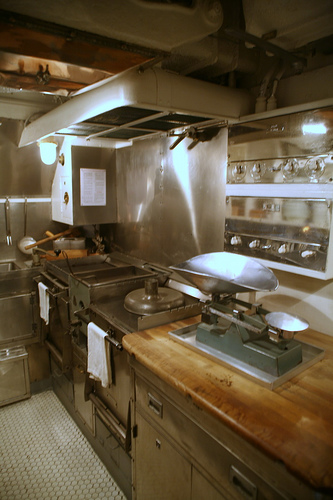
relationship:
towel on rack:
[86, 321, 113, 390] [72, 304, 125, 350]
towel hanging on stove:
[32, 285, 56, 329] [40, 260, 82, 376]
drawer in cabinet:
[115, 385, 208, 452] [127, 422, 205, 483]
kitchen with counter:
[17, 94, 320, 485] [159, 347, 301, 446]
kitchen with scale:
[17, 94, 320, 485] [162, 265, 287, 380]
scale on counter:
[158, 267, 316, 405] [152, 300, 313, 448]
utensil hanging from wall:
[5, 198, 14, 247] [0, 186, 44, 208]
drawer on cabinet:
[137, 379, 274, 499] [128, 358, 332, 498]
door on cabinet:
[131, 407, 191, 498] [128, 358, 332, 498]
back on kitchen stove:
[118, 126, 228, 284] [69, 250, 200, 489]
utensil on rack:
[3, 195, 13, 247] [0, 195, 54, 204]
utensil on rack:
[17, 193, 40, 254] [0, 195, 54, 204]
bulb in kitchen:
[38, 138, 58, 166] [0, 1, 332, 498]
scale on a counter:
[165, 248, 310, 378] [119, 285, 332, 496]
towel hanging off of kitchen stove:
[81, 320, 115, 399] [69, 250, 200, 489]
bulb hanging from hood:
[33, 138, 60, 173] [15, 76, 247, 154]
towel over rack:
[86, 321, 113, 390] [72, 304, 125, 350]